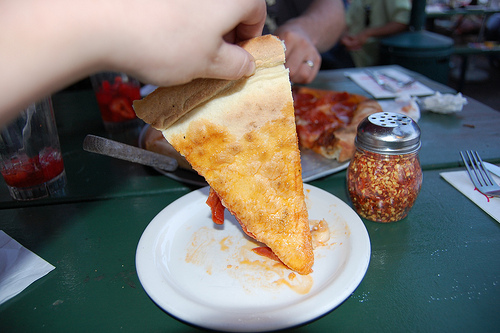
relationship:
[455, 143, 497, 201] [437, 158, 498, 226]
fork head on napkin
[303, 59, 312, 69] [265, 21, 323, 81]
ring on hand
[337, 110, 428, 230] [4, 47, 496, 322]
bottle on table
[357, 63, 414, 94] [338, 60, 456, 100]
silverware on napkin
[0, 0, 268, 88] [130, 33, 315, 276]
hand holding pizza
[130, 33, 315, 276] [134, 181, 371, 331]
pizza is over plate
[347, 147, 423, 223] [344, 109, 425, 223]
flakes is in pepper shaker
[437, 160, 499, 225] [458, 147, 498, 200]
napkin is under fork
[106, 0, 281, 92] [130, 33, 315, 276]
hand is grasping pizza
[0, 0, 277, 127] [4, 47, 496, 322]
person sitting at table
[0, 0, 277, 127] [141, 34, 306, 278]
person eating pizza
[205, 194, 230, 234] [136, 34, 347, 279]
toppings sliding off slice